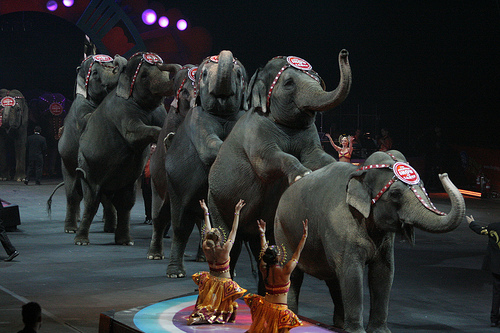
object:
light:
[142, 9, 157, 25]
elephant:
[46, 53, 128, 235]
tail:
[45, 181, 65, 219]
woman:
[187, 198, 248, 326]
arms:
[226, 212, 239, 250]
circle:
[392, 161, 419, 186]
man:
[27, 125, 50, 184]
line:
[43, 33, 465, 332]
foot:
[65, 219, 81, 233]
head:
[74, 53, 130, 102]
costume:
[182, 270, 247, 324]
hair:
[203, 232, 220, 250]